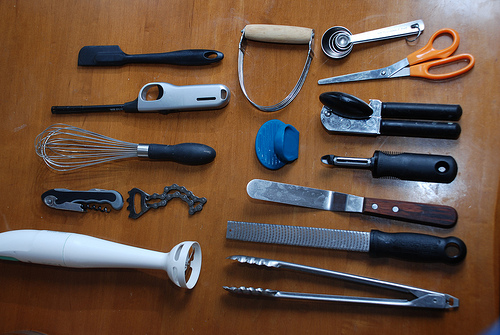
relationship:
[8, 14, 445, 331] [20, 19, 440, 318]
tools in kitchen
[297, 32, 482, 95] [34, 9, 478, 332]
scissor on table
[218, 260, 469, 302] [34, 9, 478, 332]
tong on table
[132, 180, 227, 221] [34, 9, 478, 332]
bottle opener on table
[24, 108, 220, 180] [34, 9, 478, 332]
eggbeater on table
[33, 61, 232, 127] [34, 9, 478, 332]
lighter on table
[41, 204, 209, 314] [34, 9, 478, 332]
brush on table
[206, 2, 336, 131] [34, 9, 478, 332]
server on table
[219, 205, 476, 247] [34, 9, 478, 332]
scraper on table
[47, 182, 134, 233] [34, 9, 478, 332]
whisk on table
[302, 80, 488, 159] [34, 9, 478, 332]
can opener on table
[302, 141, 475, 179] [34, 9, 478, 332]
peeler on table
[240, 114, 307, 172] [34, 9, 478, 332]
spatual on table